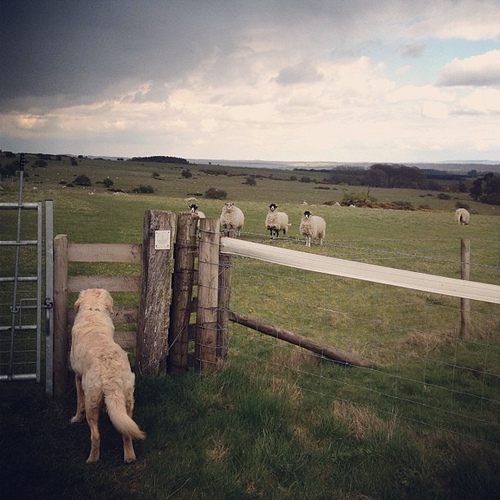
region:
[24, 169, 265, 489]
a dog standing outside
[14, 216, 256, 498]
a dog looking through a fence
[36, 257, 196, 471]
a dog looking through a wooden fence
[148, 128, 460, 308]
sheep in a field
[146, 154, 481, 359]
sheep standing in a field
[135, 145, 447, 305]
sheep standing in the grass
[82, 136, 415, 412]
sheep fenced in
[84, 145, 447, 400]
sheep behind a fence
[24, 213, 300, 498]
a dog behind a fence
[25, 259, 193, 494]
a dog standing in grass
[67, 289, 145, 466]
a furry white sheep dog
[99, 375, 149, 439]
the tail of a sheep dog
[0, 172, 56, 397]
a grey metal gate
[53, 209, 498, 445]
a wood and wire fence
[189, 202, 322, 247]
a group of four sheep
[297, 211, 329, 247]
a wooly white sheep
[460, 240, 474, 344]
a lone fence post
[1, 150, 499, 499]
a large field of grass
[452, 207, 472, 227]
a lone sheep in a field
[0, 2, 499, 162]
a cloudy sky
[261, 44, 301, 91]
part of a cloud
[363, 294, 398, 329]
part of a fence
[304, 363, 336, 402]
part of a ground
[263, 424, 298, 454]
part of a grass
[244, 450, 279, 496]
part of a grass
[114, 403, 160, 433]
part of a tail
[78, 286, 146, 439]
A dog watching the sheep.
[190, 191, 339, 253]
Sheep in the field.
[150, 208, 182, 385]
A wooden pole on the fence.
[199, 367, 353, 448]
The grass is green and brown.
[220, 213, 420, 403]
A wire gate surrounding the sheep.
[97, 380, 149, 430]
The dog tail is wagging.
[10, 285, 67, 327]
A lock on the gate.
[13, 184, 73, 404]
Iron gate next to the dog.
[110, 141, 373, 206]
Trees in the background.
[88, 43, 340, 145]
The sky is full of clouds.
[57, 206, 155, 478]
a big white dog standing next to a gate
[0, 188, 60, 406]
a metal gate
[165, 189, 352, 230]
four sheep standing in a field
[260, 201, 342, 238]
two white sheep with black faces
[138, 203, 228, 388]
three wood post in the ground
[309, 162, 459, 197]
a area of trees in a the middle of a field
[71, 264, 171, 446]
a white dog with a long tail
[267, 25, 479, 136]
white clouds in a blue sky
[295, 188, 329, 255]
a white sheep with a black face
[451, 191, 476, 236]
a sheep grazing in a field